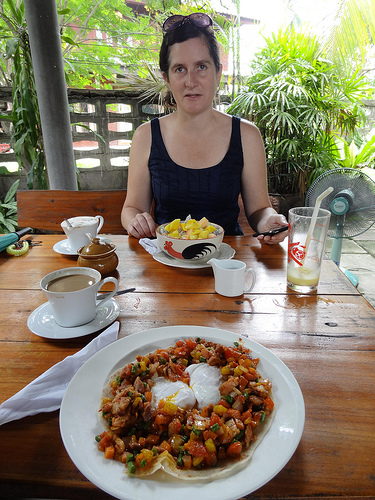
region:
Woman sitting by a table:
[121, 18, 294, 239]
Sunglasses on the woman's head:
[159, 12, 213, 34]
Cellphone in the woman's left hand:
[252, 223, 288, 235]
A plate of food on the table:
[60, 324, 305, 498]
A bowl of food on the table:
[154, 211, 222, 259]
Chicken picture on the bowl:
[160, 240, 214, 258]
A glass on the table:
[286, 207, 330, 292]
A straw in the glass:
[297, 185, 333, 273]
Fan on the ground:
[305, 169, 374, 290]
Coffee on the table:
[39, 265, 118, 327]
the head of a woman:
[150, 7, 226, 121]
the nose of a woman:
[181, 66, 192, 87]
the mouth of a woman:
[177, 83, 202, 106]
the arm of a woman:
[234, 120, 274, 220]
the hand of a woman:
[123, 210, 160, 241]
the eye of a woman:
[192, 60, 207, 72]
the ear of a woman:
[214, 61, 226, 85]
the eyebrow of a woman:
[192, 57, 216, 68]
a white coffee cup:
[36, 259, 123, 331]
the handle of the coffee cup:
[95, 271, 120, 307]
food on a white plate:
[88, 332, 286, 488]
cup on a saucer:
[35, 264, 122, 329]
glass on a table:
[278, 198, 336, 301]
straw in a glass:
[297, 182, 337, 275]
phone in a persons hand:
[248, 222, 290, 243]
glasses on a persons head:
[155, 8, 219, 43]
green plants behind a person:
[219, 15, 347, 233]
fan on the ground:
[301, 165, 373, 288]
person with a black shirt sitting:
[114, 8, 295, 246]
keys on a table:
[5, 235, 45, 257]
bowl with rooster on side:
[151, 220, 232, 274]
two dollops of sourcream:
[146, 355, 240, 428]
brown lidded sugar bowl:
[70, 232, 126, 282]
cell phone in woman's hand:
[248, 207, 288, 260]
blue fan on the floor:
[301, 159, 374, 295]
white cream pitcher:
[206, 252, 260, 309]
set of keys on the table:
[2, 228, 43, 262]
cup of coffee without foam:
[24, 264, 127, 337]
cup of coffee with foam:
[46, 202, 110, 259]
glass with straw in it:
[288, 172, 329, 310]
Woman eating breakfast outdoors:
[97, 35, 278, 268]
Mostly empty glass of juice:
[292, 180, 337, 303]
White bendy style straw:
[296, 166, 349, 286]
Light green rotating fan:
[289, 152, 370, 280]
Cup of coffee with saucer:
[18, 255, 141, 338]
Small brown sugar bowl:
[60, 235, 134, 294]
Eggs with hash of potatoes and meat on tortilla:
[105, 331, 258, 497]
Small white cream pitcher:
[193, 243, 267, 314]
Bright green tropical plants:
[253, 8, 373, 174]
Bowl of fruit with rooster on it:
[141, 206, 247, 272]